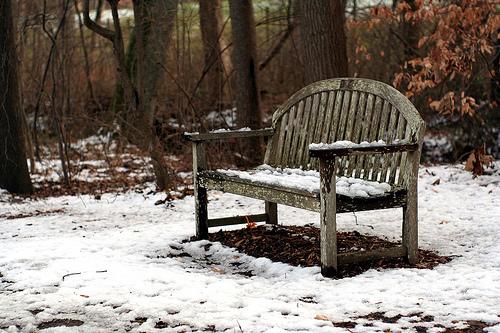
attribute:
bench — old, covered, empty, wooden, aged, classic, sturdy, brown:
[183, 78, 427, 276]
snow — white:
[218, 162, 391, 199]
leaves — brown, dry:
[208, 224, 448, 273]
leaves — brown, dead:
[347, 1, 498, 114]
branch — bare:
[92, 117, 132, 144]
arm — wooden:
[308, 140, 419, 194]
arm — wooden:
[183, 127, 273, 170]